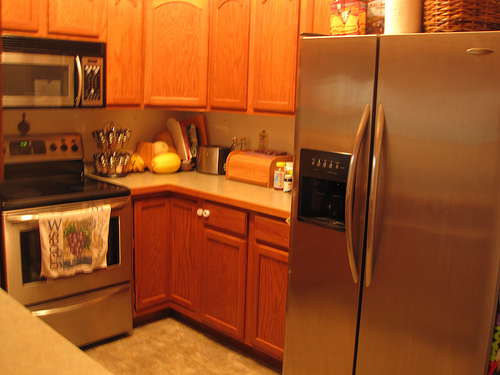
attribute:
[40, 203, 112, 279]
towel — white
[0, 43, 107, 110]
microwave — stajnless steel, stainless steel, black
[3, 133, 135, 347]
stove — stainless steel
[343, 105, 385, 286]
handles — metal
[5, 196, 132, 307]
oven — silver, black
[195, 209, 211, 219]
cupboard handles — white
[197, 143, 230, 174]
toaster — metallic, stainless steel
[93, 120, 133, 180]
spice rack — rotating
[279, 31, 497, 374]
fridge — stainless steel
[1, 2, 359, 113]
cabinets — wooden, light wood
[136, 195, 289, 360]
cupboards — wooden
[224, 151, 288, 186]
bread box — wooden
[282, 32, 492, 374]
door — stainless steel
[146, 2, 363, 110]
cabinet doors — wooden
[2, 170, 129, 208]
top of stove — stainless steel